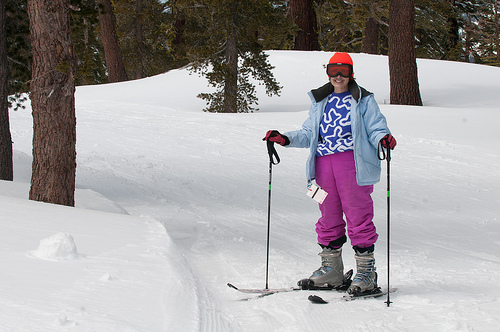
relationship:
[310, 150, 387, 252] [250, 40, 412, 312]
pants on skier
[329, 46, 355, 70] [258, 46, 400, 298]
cap on girl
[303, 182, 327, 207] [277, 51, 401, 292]
tag on skier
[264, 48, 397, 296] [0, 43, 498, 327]
skiier standing in snow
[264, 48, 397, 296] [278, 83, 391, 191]
skiier wearing jacket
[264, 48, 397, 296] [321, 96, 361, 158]
skiier wearing shirt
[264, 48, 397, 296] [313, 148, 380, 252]
skiier wearing pants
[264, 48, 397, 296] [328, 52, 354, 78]
skiier wearing cap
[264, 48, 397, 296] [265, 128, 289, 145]
skiier wearing glove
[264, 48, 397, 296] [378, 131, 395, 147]
skiier wearing glove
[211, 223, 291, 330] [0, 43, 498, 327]
track in snow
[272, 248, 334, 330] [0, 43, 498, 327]
track in snow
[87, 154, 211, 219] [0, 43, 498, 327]
track in snow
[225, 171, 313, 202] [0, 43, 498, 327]
track in snow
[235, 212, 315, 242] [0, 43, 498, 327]
track in snow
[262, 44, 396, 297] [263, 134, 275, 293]
skiier holding poles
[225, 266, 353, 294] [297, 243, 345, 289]
ski under boot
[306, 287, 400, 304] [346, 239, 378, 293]
ski under boot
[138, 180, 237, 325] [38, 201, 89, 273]
tracks in snow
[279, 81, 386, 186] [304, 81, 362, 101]
jacket has collar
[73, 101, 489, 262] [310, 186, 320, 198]
slope pass on zipper pull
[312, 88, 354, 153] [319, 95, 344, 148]
shirt has lines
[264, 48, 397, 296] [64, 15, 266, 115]
skiier skis in woods